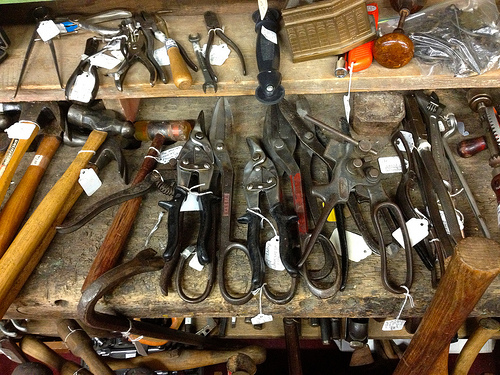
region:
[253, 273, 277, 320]
edge fo a handle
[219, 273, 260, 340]
part of a scissor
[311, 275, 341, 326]
edge fo a handle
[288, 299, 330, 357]
edge fo a shelf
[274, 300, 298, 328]
part of a boarf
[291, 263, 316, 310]
part of a handle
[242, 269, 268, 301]
part of an edge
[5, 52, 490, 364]
Tools lying on a wooden shelf.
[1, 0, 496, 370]
White tags attached to tools.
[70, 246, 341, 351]
A crowbar on the endge of the table.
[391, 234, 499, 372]
A rounded wooden handle.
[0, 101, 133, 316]
Hammers with brown wooden handles.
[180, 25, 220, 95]
A silver wrench.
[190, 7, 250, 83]
A pair of pliers.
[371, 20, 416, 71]
A shiny brown knob.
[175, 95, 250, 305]
A silver cutting tool.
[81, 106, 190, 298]
A mallet with a wooden handle.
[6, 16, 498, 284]
tools on two shelves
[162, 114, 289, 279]
two pairs of pliers with black handles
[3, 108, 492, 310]
lower shelf with tools on it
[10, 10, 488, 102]
secon shelf with tools on it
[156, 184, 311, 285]
black handles of two pliers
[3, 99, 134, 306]
four hammers on left side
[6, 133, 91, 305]
four wood handles of hammers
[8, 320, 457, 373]
tools under the shelves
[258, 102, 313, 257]
pliers with red handle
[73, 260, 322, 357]
pry bar hanging off shelf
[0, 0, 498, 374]
the various tools spread out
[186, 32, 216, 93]
the wrench on the shelf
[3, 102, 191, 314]
the group of hammers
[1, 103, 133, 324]
the hammer on the table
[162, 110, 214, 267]
the pair of pliers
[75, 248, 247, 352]
the crow bar hanging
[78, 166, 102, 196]
the little white tag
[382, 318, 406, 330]
the little white tag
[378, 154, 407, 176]
the little white tag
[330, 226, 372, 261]
the little white tag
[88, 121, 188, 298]
A mallet among the tools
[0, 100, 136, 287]
A hammer near a mallet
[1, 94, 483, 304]
Assorted tools on the table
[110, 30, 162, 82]
A hole puncher on the shelf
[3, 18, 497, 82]
A shelf full of tools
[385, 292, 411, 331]
A tag on a tool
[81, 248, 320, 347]
A crowbar on the shelf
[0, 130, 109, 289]
The handle of the hammer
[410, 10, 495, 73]
A plastic bag full of tools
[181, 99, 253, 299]
Shears on the shelf